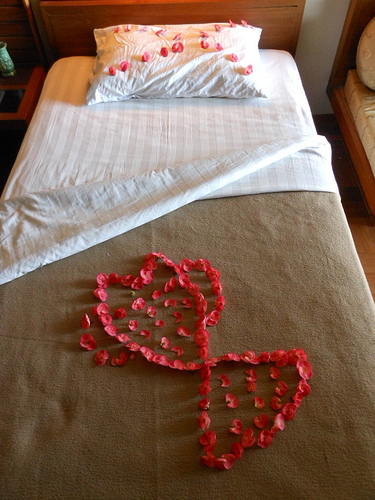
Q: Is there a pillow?
A: Yes, there is a pillow.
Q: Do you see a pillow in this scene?
A: Yes, there is a pillow.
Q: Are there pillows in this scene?
A: Yes, there is a pillow.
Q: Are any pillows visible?
A: Yes, there is a pillow.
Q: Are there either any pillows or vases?
A: Yes, there is a pillow.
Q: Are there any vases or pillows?
A: Yes, there is a pillow.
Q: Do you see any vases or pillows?
A: Yes, there is a pillow.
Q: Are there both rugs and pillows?
A: No, there is a pillow but no rugs.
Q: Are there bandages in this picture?
A: No, there are no bandages.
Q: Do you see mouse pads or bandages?
A: No, there are no bandages or mouse pads.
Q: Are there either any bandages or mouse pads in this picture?
A: No, there are no bandages or mouse pads.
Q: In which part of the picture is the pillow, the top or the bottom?
A: The pillow is in the top of the image.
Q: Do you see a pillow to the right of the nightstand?
A: Yes, there is a pillow to the right of the nightstand.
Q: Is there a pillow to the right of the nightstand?
A: Yes, there is a pillow to the right of the nightstand.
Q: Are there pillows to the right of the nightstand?
A: Yes, there is a pillow to the right of the nightstand.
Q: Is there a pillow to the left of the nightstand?
A: No, the pillow is to the right of the nightstand.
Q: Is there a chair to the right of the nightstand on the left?
A: No, there is a pillow to the right of the nightstand.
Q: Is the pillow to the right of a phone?
A: No, the pillow is to the right of the nightstand.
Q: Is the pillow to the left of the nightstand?
A: No, the pillow is to the right of the nightstand.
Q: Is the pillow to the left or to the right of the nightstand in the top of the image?
A: The pillow is to the right of the nightstand.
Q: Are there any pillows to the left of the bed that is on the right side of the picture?
A: Yes, there is a pillow to the left of the bed.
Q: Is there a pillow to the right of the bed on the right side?
A: No, the pillow is to the left of the bed.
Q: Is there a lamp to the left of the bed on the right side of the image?
A: No, there is a pillow to the left of the bed.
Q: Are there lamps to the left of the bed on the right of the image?
A: No, there is a pillow to the left of the bed.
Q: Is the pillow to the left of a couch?
A: No, the pillow is to the left of a bed.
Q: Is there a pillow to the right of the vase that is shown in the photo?
A: Yes, there is a pillow to the right of the vase.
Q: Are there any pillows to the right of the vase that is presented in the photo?
A: Yes, there is a pillow to the right of the vase.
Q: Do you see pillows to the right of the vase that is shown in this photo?
A: Yes, there is a pillow to the right of the vase.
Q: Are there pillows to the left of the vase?
A: No, the pillow is to the right of the vase.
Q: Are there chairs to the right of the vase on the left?
A: No, there is a pillow to the right of the vase.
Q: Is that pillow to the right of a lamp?
A: No, the pillow is to the right of a vase.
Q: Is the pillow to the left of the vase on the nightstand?
A: No, the pillow is to the right of the vase.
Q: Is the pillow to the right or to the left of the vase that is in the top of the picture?
A: The pillow is to the right of the vase.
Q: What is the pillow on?
A: The pillow is on the bed.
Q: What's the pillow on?
A: The pillow is on the bed.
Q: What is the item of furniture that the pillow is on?
A: The piece of furniture is a bed.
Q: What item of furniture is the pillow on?
A: The pillow is on the bed.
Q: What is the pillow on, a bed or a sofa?
A: The pillow is on a bed.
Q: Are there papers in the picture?
A: No, there are no papers.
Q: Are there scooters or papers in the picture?
A: No, there are no papers or scooters.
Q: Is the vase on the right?
A: No, the vase is on the left of the image.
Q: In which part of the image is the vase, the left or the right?
A: The vase is on the left of the image.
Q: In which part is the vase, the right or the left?
A: The vase is on the left of the image.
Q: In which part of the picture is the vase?
A: The vase is on the left of the image.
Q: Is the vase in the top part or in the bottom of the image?
A: The vase is in the top of the image.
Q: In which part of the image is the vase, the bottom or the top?
A: The vase is in the top of the image.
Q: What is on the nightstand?
A: The vase is on the nightstand.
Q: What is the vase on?
A: The vase is on the nightstand.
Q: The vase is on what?
A: The vase is on the nightstand.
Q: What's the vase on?
A: The vase is on the nightstand.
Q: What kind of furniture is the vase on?
A: The vase is on the nightstand.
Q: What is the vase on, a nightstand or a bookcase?
A: The vase is on a nightstand.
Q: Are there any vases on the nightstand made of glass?
A: Yes, there is a vase on the nightstand.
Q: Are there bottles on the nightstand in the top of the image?
A: No, there is a vase on the nightstand.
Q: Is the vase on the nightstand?
A: Yes, the vase is on the nightstand.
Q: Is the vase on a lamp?
A: No, the vase is on the nightstand.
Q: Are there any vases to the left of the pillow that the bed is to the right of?
A: Yes, there is a vase to the left of the pillow.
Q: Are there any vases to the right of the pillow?
A: No, the vase is to the left of the pillow.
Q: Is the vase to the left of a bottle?
A: No, the vase is to the left of the pillow.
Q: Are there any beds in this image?
A: Yes, there is a bed.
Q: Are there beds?
A: Yes, there is a bed.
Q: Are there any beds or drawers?
A: Yes, there is a bed.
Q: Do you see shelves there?
A: No, there are no shelves.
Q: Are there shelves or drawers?
A: No, there are no shelves or drawers.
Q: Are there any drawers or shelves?
A: No, there are no shelves or drawers.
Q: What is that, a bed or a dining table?
A: That is a bed.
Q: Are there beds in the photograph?
A: Yes, there is a bed.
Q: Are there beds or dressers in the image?
A: Yes, there is a bed.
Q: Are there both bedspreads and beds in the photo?
A: Yes, there are both a bed and a bedspread.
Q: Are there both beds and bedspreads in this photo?
A: Yes, there are both a bed and a bedspread.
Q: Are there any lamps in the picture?
A: No, there are no lamps.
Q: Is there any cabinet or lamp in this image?
A: No, there are no lamps or cabinets.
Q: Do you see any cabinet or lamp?
A: No, there are no lamps or cabinets.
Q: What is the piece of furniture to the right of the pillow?
A: The piece of furniture is a bed.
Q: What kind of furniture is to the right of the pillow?
A: The piece of furniture is a bed.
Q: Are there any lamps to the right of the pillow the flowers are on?
A: No, there is a bed to the right of the pillow.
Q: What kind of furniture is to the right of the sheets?
A: The piece of furniture is a bed.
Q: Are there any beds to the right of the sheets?
A: Yes, there is a bed to the right of the sheets.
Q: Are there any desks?
A: No, there are no desks.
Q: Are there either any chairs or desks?
A: No, there are no desks or chairs.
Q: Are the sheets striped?
A: Yes, the sheets are striped.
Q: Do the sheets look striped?
A: Yes, the sheets are striped.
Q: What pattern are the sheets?
A: The sheets are striped.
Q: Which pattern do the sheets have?
A: The sheets have striped pattern.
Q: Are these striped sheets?
A: Yes, these are striped sheets.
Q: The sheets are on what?
A: The sheets are on the bed.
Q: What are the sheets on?
A: The sheets are on the bed.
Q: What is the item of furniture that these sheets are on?
A: The piece of furniture is a bed.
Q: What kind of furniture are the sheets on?
A: The sheets are on the bed.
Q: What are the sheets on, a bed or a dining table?
A: The sheets are on a bed.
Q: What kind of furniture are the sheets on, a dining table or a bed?
A: The sheets are on a bed.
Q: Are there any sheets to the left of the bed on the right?
A: Yes, there are sheets to the left of the bed.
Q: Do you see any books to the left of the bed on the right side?
A: No, there are sheets to the left of the bed.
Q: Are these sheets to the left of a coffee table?
A: No, the sheets are to the left of the bed.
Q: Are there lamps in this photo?
A: No, there are no lamps.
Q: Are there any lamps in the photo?
A: No, there are no lamps.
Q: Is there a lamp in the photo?
A: No, there are no lamps.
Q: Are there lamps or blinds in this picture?
A: No, there are no lamps or blinds.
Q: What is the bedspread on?
A: The bedspread is on the bed.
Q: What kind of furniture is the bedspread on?
A: The bedspread is on the bed.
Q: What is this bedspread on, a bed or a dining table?
A: The bedspread is on a bed.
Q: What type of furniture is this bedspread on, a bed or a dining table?
A: The bedspread is on a bed.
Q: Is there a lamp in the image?
A: No, there are no lamps.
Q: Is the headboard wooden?
A: Yes, the headboard is wooden.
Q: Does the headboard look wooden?
A: Yes, the headboard is wooden.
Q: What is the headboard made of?
A: The head board is made of wood.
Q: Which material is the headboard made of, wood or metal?
A: The headboard is made of wood.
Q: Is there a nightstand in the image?
A: Yes, there is a nightstand.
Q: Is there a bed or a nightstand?
A: Yes, there is a nightstand.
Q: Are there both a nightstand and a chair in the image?
A: No, there is a nightstand but no chairs.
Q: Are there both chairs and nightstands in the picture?
A: No, there is a nightstand but no chairs.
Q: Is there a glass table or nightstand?
A: Yes, there is a glass nightstand.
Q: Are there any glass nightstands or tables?
A: Yes, there is a glass nightstand.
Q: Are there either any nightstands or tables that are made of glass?
A: Yes, the nightstand is made of glass.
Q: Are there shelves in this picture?
A: No, there are no shelves.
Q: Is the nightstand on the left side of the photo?
A: Yes, the nightstand is on the left of the image.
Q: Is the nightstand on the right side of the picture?
A: No, the nightstand is on the left of the image.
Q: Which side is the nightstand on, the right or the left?
A: The nightstand is on the left of the image.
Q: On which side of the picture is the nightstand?
A: The nightstand is on the left of the image.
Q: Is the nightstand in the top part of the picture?
A: Yes, the nightstand is in the top of the image.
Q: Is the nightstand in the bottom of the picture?
A: No, the nightstand is in the top of the image.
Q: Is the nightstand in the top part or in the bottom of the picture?
A: The nightstand is in the top of the image.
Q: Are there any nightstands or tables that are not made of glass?
A: No, there is a nightstand but it is made of glass.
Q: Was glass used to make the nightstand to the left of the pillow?
A: Yes, the nightstand is made of glass.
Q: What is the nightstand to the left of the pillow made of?
A: The nightstand is made of glass.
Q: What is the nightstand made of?
A: The nightstand is made of glass.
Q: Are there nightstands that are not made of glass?
A: No, there is a nightstand but it is made of glass.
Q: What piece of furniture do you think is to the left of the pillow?
A: The piece of furniture is a nightstand.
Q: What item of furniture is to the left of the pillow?
A: The piece of furniture is a nightstand.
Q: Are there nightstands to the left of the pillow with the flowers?
A: Yes, there is a nightstand to the left of the pillow.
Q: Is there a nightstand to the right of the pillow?
A: No, the nightstand is to the left of the pillow.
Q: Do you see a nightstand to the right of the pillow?
A: No, the nightstand is to the left of the pillow.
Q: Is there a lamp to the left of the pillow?
A: No, there is a nightstand to the left of the pillow.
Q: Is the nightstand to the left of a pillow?
A: Yes, the nightstand is to the left of a pillow.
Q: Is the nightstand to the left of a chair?
A: No, the nightstand is to the left of a pillow.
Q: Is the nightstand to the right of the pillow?
A: No, the nightstand is to the left of the pillow.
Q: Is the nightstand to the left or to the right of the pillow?
A: The nightstand is to the left of the pillow.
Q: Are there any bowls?
A: No, there are no bowls.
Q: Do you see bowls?
A: No, there are no bowls.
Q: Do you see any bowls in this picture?
A: No, there are no bowls.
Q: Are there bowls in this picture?
A: No, there are no bowls.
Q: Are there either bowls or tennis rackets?
A: No, there are no bowls or tennis rackets.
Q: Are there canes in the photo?
A: No, there are no canes.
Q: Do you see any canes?
A: No, there are no canes.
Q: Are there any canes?
A: No, there are no canes.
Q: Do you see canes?
A: No, there are no canes.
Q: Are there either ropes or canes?
A: No, there are no canes or ropes.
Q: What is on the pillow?
A: The flowers are on the pillow.